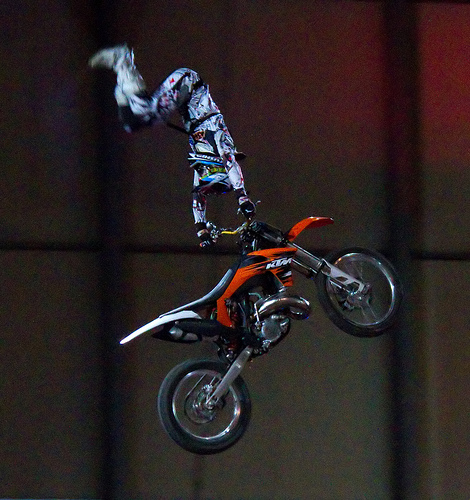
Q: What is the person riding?
A: A motorbike.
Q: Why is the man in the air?
A: Doing a trick.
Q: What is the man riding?
A: Motorcycle.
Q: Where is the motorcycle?
A: In the air.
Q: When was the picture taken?
A: During a show.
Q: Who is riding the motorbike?
A: A man.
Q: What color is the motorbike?
A: Orange.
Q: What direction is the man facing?
A: Downwards.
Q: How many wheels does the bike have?
A: Two.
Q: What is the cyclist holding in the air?
A: A motorbike.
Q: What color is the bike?
A: Orange.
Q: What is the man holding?
A: A motorcycle.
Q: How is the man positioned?
A: Upside down.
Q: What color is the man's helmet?
A: Blue.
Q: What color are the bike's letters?
A: White.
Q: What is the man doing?
A: Performing.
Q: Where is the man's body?
A: Over the bike.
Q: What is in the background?
A: A wall.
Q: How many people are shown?
A: One.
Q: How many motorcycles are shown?
A: One.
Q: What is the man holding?
A: A motorcycle.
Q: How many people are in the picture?
A: One.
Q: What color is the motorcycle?
A: Orange.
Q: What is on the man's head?
A: A helmet.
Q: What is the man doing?
A: A motorcycle trick.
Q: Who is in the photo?
A: A man.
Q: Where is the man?
A: In the air.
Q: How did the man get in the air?
A: Jumped with a motorcycle.